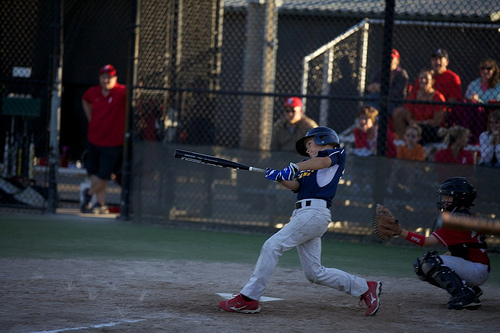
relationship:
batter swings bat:
[221, 122, 385, 321] [171, 148, 287, 182]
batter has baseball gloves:
[221, 122, 385, 321] [266, 162, 306, 183]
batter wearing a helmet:
[221, 122, 385, 321] [289, 124, 344, 155]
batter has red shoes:
[221, 122, 385, 321] [216, 278, 385, 318]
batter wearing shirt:
[221, 122, 385, 321] [294, 149, 350, 204]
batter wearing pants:
[221, 122, 385, 321] [240, 198, 371, 303]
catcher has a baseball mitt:
[373, 172, 495, 312] [368, 202, 405, 245]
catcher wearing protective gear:
[373, 172, 495, 312] [411, 253, 480, 309]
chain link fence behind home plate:
[127, 4, 499, 248] [217, 287, 285, 308]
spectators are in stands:
[350, 53, 499, 162] [300, 14, 497, 170]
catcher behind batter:
[373, 172, 495, 312] [221, 122, 385, 321]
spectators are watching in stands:
[350, 53, 499, 162] [300, 14, 497, 170]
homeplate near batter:
[217, 287, 285, 308] [221, 122, 385, 321]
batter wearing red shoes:
[221, 122, 385, 321] [216, 278, 385, 318]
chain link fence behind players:
[127, 4, 499, 248] [148, 114, 497, 324]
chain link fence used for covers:
[127, 4, 499, 248] [120, 0, 496, 37]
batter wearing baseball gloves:
[221, 122, 385, 321] [266, 162, 306, 183]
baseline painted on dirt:
[24, 307, 139, 331] [5, 258, 499, 332]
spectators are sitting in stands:
[350, 53, 499, 162] [300, 14, 497, 170]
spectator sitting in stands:
[268, 98, 323, 152] [300, 14, 497, 170]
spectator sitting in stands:
[418, 46, 469, 101] [300, 14, 497, 170]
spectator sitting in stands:
[463, 56, 499, 102] [300, 14, 497, 170]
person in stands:
[404, 70, 449, 139] [300, 14, 497, 170]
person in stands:
[433, 124, 481, 167] [300, 14, 497, 170]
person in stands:
[476, 108, 499, 158] [300, 14, 497, 170]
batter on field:
[221, 122, 385, 321] [0, 210, 493, 330]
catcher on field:
[373, 172, 495, 312] [0, 210, 493, 330]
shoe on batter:
[213, 292, 273, 318] [221, 122, 385, 321]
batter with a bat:
[221, 122, 385, 321] [171, 148, 287, 182]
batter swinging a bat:
[221, 122, 385, 321] [171, 148, 287, 182]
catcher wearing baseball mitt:
[373, 172, 495, 312] [368, 202, 405, 245]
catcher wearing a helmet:
[373, 172, 495, 312] [428, 173, 481, 213]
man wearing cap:
[75, 62, 133, 218] [94, 64, 119, 80]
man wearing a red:
[75, 62, 133, 218] [82, 82, 124, 145]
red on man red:
[82, 82, 124, 145] [99, 111, 122, 128]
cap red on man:
[94, 64, 119, 80] [75, 62, 133, 218]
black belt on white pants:
[290, 195, 336, 213] [240, 198, 371, 303]